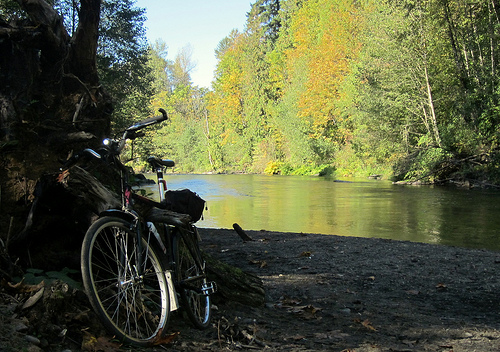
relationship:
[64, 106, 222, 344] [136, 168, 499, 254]
bike next to lake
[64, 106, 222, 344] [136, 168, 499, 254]
bike at lake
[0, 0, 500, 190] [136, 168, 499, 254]
trees line lake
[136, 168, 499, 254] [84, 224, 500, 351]
lake has bank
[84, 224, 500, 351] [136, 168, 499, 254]
bank next to lake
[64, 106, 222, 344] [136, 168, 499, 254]
bike near lake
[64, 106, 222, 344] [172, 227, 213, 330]
bike has tire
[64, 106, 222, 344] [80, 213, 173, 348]
bike has tire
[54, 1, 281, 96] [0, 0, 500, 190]
sky behind trees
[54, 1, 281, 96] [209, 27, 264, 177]
sky behind tree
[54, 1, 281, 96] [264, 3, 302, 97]
sky behind tree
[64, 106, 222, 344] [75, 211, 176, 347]
bike has wheel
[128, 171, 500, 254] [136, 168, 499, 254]
water in lake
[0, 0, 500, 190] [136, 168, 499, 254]
trees surround lake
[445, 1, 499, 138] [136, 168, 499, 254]
tree next to lake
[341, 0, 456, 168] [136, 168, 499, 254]
tree next to lake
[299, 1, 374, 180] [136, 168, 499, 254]
tree next to lake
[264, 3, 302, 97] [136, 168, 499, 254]
tree next to lake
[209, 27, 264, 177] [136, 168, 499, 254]
tree next to lake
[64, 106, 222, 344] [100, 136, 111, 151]
bike has bell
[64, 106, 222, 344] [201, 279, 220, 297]
bike has pedal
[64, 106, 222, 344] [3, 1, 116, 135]
bike leaning against tree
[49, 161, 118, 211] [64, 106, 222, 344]
trunk by bike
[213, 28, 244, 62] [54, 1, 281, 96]
treetop against sky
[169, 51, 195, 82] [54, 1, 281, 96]
treetop against sky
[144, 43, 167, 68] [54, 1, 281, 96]
treetop against sky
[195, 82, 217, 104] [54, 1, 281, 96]
treetop against sky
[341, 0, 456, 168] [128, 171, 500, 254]
tree near water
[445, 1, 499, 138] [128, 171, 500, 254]
tree near water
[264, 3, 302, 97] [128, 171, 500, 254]
tree near water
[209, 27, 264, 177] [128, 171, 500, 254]
tree near water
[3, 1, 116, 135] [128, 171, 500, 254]
tree near water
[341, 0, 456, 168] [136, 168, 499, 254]
tree on edge of lake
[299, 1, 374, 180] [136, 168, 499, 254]
tree reflected in lake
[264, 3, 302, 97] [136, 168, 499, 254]
tree reflected in lake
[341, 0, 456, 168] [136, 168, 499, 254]
tree reflected in lake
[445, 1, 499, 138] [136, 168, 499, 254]
tree reflected in lake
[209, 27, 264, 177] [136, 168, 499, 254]
tree reflected in lake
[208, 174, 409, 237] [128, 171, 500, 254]
reflection in water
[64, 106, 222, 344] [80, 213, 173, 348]
bike has front wheel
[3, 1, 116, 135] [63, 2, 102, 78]
tree has trunk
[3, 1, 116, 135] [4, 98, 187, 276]
tree grows out of hill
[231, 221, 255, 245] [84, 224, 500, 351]
tree stump sticking out of bank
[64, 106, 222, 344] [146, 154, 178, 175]
bike has seat